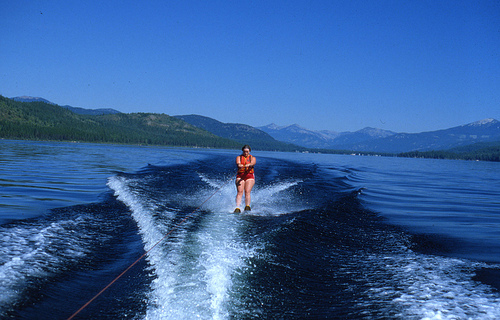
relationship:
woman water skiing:
[232, 147, 256, 214] [232, 208, 251, 220]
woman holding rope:
[232, 147, 256, 214] [70, 165, 247, 319]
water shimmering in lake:
[186, 240, 248, 303] [0, 140, 497, 319]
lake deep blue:
[0, 140, 497, 319] [128, 152, 162, 165]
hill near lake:
[33, 105, 97, 138] [0, 140, 497, 319]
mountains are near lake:
[367, 127, 475, 154] [0, 140, 497, 319]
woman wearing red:
[232, 147, 256, 214] [245, 170, 254, 179]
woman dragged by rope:
[232, 147, 256, 214] [70, 165, 247, 319]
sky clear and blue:
[231, 21, 322, 90] [128, 152, 162, 165]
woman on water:
[232, 147, 256, 214] [186, 240, 248, 303]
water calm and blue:
[186, 240, 248, 303] [128, 152, 162, 165]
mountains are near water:
[367, 127, 475, 154] [186, 240, 248, 303]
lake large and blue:
[19, 145, 56, 169] [128, 152, 162, 165]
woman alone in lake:
[232, 147, 256, 214] [0, 140, 497, 319]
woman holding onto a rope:
[232, 147, 256, 214] [199, 186, 222, 204]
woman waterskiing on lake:
[232, 147, 256, 214] [19, 145, 56, 169]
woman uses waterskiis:
[232, 147, 256, 214] [230, 205, 252, 214]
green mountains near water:
[9, 108, 30, 124] [186, 240, 248, 303]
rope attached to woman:
[199, 186, 222, 204] [232, 147, 256, 214]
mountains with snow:
[367, 127, 475, 154] [476, 117, 491, 126]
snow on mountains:
[476, 117, 491, 126] [367, 127, 475, 154]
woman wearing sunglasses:
[232, 147, 256, 214] [241, 147, 249, 156]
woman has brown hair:
[232, 147, 256, 214] [243, 144, 248, 148]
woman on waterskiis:
[232, 147, 256, 214] [230, 205, 252, 214]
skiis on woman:
[230, 205, 252, 214] [232, 147, 256, 214]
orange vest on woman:
[243, 158, 248, 164] [232, 147, 256, 214]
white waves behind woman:
[260, 179, 294, 198] [232, 147, 256, 214]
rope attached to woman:
[70, 165, 247, 319] [232, 147, 256, 214]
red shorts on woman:
[245, 170, 254, 179] [232, 147, 256, 214]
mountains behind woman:
[367, 127, 475, 154] [232, 147, 256, 214]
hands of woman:
[239, 163, 251, 170] [232, 147, 256, 214]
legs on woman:
[235, 177, 255, 211] [232, 147, 256, 214]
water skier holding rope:
[186, 240, 248, 303] [199, 186, 222, 204]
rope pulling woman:
[199, 186, 222, 204] [232, 147, 256, 214]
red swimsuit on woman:
[245, 170, 254, 179] [232, 147, 256, 214]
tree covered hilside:
[155, 130, 167, 145] [74, 112, 121, 136]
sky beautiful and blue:
[231, 21, 322, 90] [128, 152, 162, 165]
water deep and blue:
[186, 240, 248, 303] [128, 152, 162, 165]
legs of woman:
[235, 177, 255, 211] [232, 147, 256, 214]